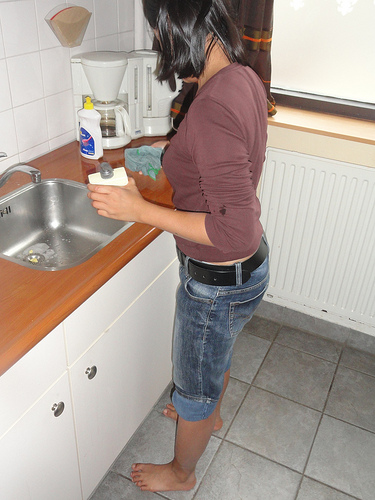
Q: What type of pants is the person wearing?
A: Blue jeans.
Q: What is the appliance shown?
A: Coffee pot.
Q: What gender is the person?
A: Female.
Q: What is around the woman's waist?
A: Belt.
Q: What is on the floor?
A: Tile.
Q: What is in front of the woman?
A: Sink.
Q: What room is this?
A: Kitchen.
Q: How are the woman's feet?
A: Bare.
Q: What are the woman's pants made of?
A: Denim.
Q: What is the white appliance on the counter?
A: Coffee maker.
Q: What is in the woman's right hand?
A: Cleaning sponge.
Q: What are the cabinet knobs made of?
A: Metal.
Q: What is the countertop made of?
A: Wood.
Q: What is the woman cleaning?
A: Sink.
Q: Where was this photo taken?
A: In a kitchen.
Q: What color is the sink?
A: Silver.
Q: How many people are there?
A: One.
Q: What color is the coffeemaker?
A: White.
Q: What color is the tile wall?
A: White.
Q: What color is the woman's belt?
A: Black.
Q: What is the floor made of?
A: Square tiles.